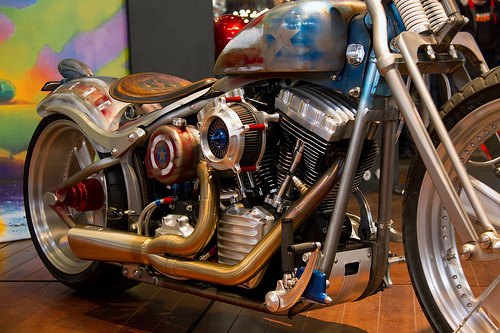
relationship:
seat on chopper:
[108, 72, 218, 104] [23, 1, 497, 331]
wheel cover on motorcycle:
[33, 75, 130, 130] [30, 17, 482, 331]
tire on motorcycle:
[400, 68, 498, 329] [30, 17, 482, 331]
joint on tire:
[44, 175, 111, 213] [18, 107, 151, 303]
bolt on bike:
[344, 41, 364, 66] [22, 0, 497, 331]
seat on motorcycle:
[108, 70, 217, 103] [30, 17, 482, 331]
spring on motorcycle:
[393, 2, 429, 30] [30, 17, 482, 331]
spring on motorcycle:
[423, 0, 448, 32] [30, 17, 482, 331]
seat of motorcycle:
[108, 72, 218, 104] [23, 9, 498, 315]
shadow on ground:
[129, 284, 216, 331] [316, 299, 380, 331]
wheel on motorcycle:
[21, 113, 138, 295] [30, 17, 482, 331]